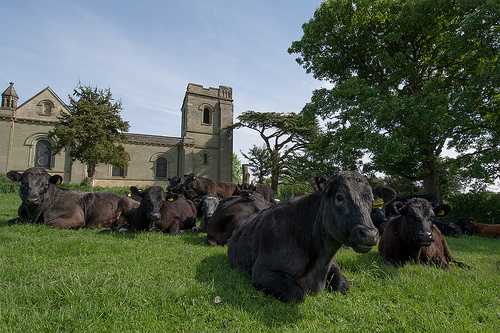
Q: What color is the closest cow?
A: Black.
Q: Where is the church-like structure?
A: In the distance, past the cows.